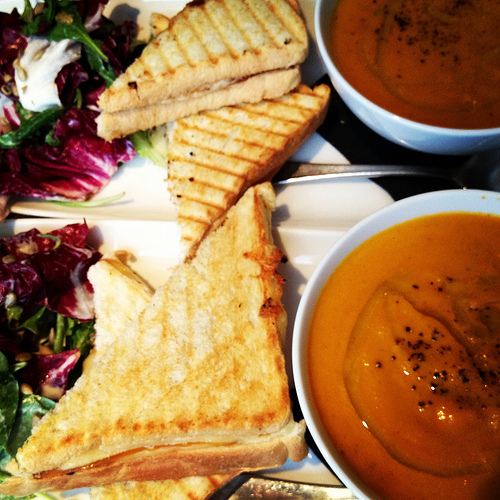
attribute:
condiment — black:
[370, 279, 499, 405]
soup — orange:
[309, 213, 499, 496]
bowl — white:
[291, 191, 499, 499]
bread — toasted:
[172, 84, 329, 256]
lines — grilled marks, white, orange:
[172, 94, 314, 240]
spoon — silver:
[267, 153, 499, 186]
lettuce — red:
[2, 99, 137, 201]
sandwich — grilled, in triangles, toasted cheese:
[18, 184, 307, 491]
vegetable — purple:
[0, 220, 100, 395]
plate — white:
[2, 0, 497, 499]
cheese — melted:
[167, 76, 233, 120]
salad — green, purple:
[0, 0, 163, 213]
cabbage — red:
[4, 222, 99, 326]